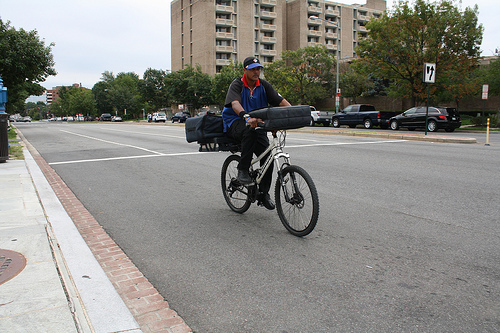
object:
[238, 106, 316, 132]
pizza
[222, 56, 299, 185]
man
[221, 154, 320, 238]
black wheels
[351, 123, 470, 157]
raised median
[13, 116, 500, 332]
street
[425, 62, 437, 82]
sign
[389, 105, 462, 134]
dark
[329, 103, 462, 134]
truck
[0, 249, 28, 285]
cover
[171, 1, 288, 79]
building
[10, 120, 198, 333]
pavement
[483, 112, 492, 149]
bright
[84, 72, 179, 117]
variety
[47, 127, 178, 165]
lines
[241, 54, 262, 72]
black red white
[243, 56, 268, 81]
head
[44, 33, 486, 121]
trees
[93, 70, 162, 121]
green tree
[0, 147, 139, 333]
gray sidewalk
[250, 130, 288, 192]
white bike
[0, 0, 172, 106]
white sky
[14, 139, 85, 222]
edge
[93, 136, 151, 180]
road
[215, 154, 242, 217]
part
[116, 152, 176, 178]
part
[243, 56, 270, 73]
cap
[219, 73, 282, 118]
black red white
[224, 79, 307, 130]
shirt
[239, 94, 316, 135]
pizza carrier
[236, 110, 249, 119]
wristband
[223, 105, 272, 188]
pair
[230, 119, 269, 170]
black pants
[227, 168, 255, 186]
shoe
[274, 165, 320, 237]
black wheel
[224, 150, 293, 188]
silver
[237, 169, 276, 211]
shoes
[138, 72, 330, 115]
background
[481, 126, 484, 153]
pole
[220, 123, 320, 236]
bike